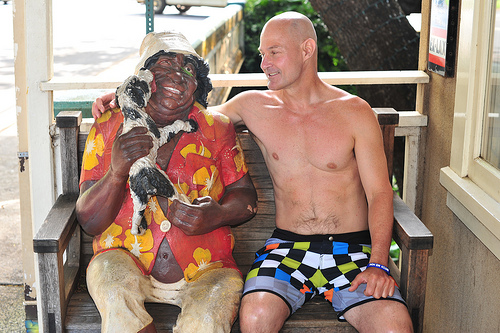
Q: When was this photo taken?
A: During the daytime.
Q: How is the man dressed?
A: In shorts.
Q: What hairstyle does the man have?
A: Bald.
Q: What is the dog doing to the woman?
A: Licking her.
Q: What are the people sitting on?
A: A bench.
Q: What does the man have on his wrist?
A: A bracelet.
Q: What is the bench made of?
A: Wood.